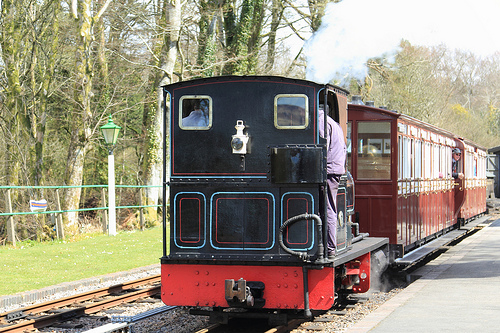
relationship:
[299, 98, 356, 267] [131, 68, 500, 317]
man on train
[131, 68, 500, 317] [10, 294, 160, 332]
train on tracks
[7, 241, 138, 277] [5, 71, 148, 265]
grass in background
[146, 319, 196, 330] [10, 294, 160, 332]
gravel by tracks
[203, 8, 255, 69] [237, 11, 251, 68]
tree with leaves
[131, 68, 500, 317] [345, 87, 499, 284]
train with cars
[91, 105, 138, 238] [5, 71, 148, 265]
lamp in background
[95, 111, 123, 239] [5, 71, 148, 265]
post in background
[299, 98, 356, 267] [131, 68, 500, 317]
man controlling engine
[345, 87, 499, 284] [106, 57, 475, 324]
middle car closest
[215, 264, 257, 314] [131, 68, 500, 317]
hitch on engine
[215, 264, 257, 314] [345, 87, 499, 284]
hitch pulls cars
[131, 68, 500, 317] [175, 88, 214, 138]
engine has window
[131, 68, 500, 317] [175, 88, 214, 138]
engine with window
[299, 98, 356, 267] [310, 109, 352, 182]
man showing back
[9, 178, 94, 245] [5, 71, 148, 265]
fence in background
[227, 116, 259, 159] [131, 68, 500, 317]
light on engine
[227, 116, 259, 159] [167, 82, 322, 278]
light on front